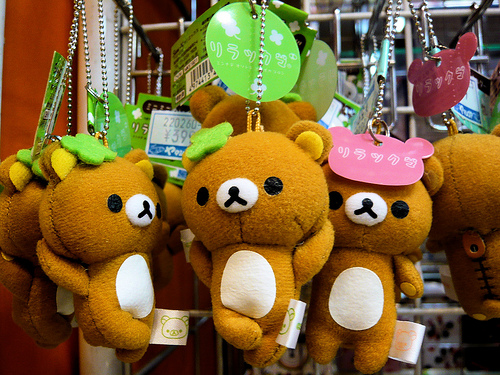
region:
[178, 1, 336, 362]
bear on a keychain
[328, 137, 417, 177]
Japanese writing on the tag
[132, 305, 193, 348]
tag hanging off the bear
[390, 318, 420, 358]
drawing of a bear's face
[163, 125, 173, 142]
small yen symbol on the tag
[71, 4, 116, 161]
silver chain hanging off the top of the bear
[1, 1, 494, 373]
bear keychains on display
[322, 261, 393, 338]
white circle on the stomach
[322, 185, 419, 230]
two black eyes on either side of the nose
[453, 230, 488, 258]
zipper on the back of the bear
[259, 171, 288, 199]
EYE OF STUFFED BEAR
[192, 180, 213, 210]
EYE OF STUFFED BEAR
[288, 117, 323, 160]
EAR OF STUFFED BEAR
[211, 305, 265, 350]
LEG OF STUFFED BEAR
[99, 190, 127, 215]
EYE OF STUFFED BEAR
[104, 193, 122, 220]
EYE OF STUFFED BEAR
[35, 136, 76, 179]
EAR OF STUFFED BEAR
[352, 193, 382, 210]
NOSE OF STUFFED BEAR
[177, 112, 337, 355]
Gold teddy bear with green bow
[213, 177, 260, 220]
White and black nose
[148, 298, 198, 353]
A tag with picture of green bear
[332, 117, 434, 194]
Bear chain with pink bear head shape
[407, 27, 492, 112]
A gold bear with burgundy bear head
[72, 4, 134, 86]
A chain on bear head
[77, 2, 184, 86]
A metal rack holding bears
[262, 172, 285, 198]
the eye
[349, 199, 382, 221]
nose on the teddy bear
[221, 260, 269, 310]
stomach of the teddy bear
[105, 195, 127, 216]
right eye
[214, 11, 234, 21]
a reflection of light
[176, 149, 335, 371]
a teddy bear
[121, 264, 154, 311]
a white stomach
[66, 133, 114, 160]
a green shamrock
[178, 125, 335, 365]
a stuffed bear hanging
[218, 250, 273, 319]
the tummy is white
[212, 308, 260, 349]
leg of stuffed bear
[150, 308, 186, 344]
tag is white and green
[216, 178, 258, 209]
snout of the bear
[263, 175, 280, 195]
the eye is black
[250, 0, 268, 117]
the chain is silver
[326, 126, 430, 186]
pink tag on head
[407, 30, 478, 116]
the tag is pink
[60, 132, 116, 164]
the bow is green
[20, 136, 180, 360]
toy brown and white stuffed bear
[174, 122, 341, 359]
toy brown and white stuffed bear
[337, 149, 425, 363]
toy brown and white stuffed bear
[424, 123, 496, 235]
toy brown and white stuffed bear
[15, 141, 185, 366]
toy brown stuffed bear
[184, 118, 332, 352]
toy brown stuffed bear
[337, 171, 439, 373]
toy brown stuffed bear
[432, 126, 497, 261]
toy brown stuffed bear